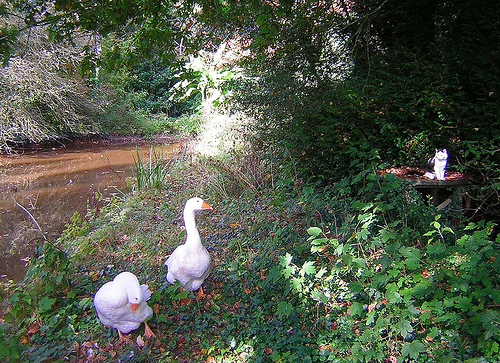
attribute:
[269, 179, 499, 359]
foliage — green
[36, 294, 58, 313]
leaf — green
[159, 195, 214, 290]
feathers — white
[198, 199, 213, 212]
beak — orange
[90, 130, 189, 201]
grass — tall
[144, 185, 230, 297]
goose — feathered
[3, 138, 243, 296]
water — brown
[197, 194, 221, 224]
beak — orange 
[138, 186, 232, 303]
goose — cleaning itself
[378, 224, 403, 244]
leaf — green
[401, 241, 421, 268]
leaf — green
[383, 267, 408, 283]
leaf — green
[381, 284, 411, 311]
leaf — green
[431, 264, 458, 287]
leaf — green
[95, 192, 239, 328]
geese — Two white 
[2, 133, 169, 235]
creek — small, brown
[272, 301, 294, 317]
leaf — green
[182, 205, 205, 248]
neck — long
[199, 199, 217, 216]
beak — orange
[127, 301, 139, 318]
beak — orange